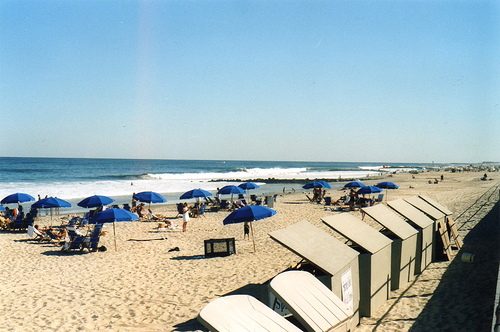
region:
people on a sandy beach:
[7, 166, 492, 326]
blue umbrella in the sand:
[216, 200, 277, 256]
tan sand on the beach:
[12, 265, 182, 316]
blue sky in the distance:
[5, 6, 486, 106]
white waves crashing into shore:
[10, 175, 212, 190]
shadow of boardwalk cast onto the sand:
[400, 180, 495, 330]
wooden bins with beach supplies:
[261, 191, 456, 316]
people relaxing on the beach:
[15, 215, 115, 250]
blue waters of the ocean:
[7, 158, 208, 170]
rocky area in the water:
[208, 171, 387, 184]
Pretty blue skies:
[24, 15, 268, 120]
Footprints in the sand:
[81, 257, 218, 312]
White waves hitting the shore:
[229, 165, 307, 186]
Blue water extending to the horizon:
[16, 160, 111, 173]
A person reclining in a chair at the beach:
[29, 223, 64, 243]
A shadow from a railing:
[335, 180, 496, 329]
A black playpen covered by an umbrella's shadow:
[198, 229, 239, 259]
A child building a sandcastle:
[152, 218, 181, 236]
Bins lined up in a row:
[304, 192, 452, 330]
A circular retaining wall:
[229, 160, 391, 188]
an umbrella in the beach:
[91, 202, 136, 252]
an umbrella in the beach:
[222, 193, 277, 248]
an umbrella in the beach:
[129, 175, 166, 223]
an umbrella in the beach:
[178, 180, 210, 222]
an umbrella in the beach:
[215, 175, 250, 219]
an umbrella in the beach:
[237, 174, 264, 199]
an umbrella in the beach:
[27, 187, 69, 233]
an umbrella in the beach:
[1, 185, 46, 234]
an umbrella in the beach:
[303, 165, 334, 206]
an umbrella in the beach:
[355, 175, 381, 211]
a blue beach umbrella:
[220, 196, 280, 248]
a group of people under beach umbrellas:
[9, 156, 281, 257]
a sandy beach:
[59, 235, 192, 295]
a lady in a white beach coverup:
[174, 199, 194, 231]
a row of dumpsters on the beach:
[268, 171, 458, 328]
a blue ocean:
[11, 146, 317, 181]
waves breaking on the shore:
[135, 158, 307, 187]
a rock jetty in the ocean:
[207, 170, 344, 187]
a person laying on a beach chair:
[21, 217, 51, 242]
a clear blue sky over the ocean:
[16, 54, 437, 158]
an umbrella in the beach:
[298, 175, 329, 202]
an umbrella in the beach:
[344, 176, 364, 194]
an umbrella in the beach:
[376, 174, 400, 198]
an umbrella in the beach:
[75, 191, 115, 214]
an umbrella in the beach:
[31, 195, 71, 219]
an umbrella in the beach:
[0, 189, 39, 209]